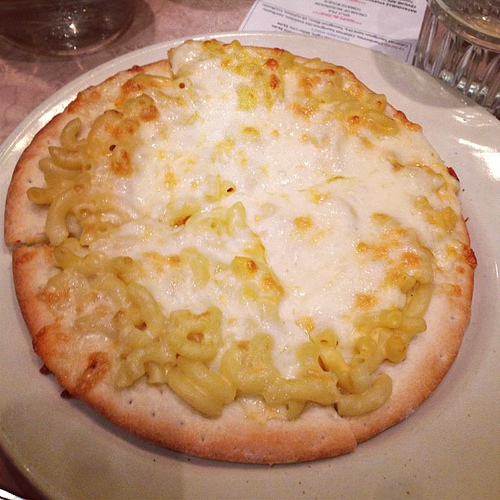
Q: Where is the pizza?
A: On the plate.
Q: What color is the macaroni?
A: Yellow.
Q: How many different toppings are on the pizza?
A: Two.